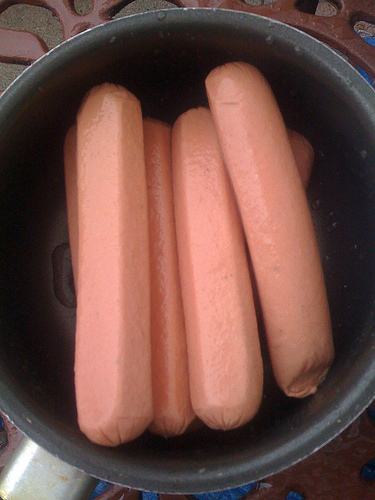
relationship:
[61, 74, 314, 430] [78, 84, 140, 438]
pile of hot dog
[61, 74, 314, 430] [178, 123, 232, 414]
pile of hot dog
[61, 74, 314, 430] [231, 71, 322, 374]
pile of hot dog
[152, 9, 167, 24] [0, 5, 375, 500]
droplet on pan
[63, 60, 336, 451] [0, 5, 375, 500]
hot dogs in pan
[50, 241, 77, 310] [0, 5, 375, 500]
water in pan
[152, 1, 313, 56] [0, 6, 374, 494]
drops on black pot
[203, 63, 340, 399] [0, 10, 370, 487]
hot dog inside pan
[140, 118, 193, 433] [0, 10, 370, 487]
hot dog inside pan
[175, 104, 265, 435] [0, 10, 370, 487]
hot dog inside pan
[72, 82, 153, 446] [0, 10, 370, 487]
hot dog inside pan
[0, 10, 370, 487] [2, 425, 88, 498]
pan has handle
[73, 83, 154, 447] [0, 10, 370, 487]
hot dog cooking pan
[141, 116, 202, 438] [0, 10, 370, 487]
hot dog cooking pan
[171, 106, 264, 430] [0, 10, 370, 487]
hot dog cooking pan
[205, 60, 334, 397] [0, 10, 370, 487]
hotdog cooking pan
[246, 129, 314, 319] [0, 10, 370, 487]
hot dogs cooking pan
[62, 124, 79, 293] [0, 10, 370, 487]
hotdog cooking pan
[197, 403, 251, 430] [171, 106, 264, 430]
lines on hot dog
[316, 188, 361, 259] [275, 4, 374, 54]
water on stove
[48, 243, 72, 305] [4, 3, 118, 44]
water on stove